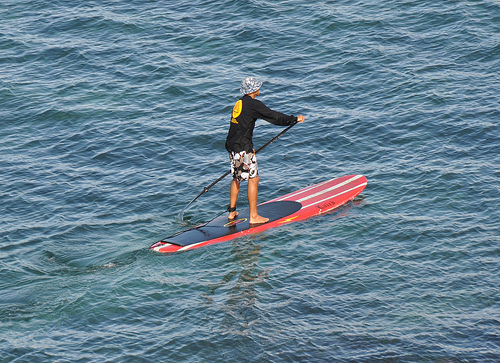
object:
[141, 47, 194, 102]
waves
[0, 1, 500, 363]
water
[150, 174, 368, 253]
board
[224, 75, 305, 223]
man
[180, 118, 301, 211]
paddle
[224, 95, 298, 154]
shirt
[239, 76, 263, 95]
hat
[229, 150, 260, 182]
shorts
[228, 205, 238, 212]
strap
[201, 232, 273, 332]
reflection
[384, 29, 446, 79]
portion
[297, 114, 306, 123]
right hand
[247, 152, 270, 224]
right leg